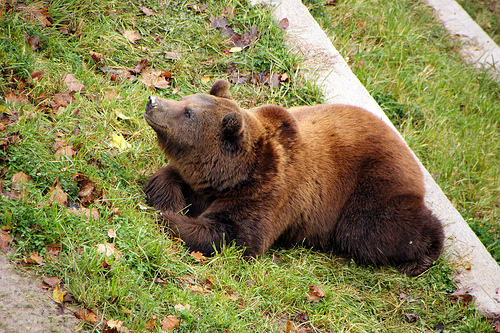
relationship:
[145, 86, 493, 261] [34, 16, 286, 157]
bear laying in grass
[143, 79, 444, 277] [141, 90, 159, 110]
bear has nose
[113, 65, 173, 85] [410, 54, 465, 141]
leaves lying on top of grass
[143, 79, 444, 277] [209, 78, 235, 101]
bear has perked up ear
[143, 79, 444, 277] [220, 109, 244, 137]
bear has perked up ear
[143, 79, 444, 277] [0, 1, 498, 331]
bear on grass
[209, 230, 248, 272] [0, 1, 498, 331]
blades of grass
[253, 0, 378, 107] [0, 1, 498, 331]
barrier in grass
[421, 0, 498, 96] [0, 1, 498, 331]
barrier in grass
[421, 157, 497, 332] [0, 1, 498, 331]
barrier in grass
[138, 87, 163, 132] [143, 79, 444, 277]
nose of bear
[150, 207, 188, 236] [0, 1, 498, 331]
paw in grass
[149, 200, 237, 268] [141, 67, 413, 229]
paw of bear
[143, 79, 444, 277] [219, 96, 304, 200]
bear has scruffy neck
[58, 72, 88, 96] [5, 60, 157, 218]
leaf in grass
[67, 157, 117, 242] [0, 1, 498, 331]
leaves spread on grass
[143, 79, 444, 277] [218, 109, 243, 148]
bear with raised ear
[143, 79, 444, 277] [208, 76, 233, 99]
bear with raised ear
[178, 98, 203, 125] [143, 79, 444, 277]
eye of bear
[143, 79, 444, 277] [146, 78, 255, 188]
bear with head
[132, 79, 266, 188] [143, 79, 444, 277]
head of bear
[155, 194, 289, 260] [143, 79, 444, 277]
leg of bear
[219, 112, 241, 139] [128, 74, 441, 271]
ear of bear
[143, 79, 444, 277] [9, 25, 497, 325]
bear lying on grass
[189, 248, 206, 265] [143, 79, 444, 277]
leaf next to bear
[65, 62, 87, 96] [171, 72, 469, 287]
leaf next to bear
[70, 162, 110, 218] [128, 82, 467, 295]
leaf next to bear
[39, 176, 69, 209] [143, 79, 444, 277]
leaf next to bear